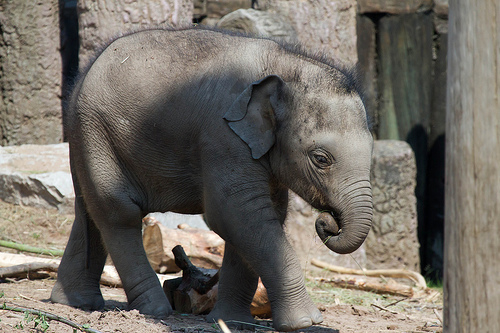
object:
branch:
[0, 239, 65, 256]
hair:
[75, 23, 371, 111]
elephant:
[47, 25, 375, 332]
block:
[278, 140, 418, 287]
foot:
[127, 291, 171, 318]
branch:
[0, 301, 89, 331]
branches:
[161, 245, 222, 315]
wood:
[157, 246, 218, 310]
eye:
[309, 150, 331, 168]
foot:
[207, 300, 258, 326]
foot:
[49, 274, 103, 309]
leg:
[72, 120, 170, 303]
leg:
[49, 140, 105, 291]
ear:
[221, 75, 295, 161]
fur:
[274, 42, 376, 116]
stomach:
[144, 176, 194, 211]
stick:
[307, 259, 429, 299]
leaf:
[3, 304, 84, 333]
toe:
[295, 307, 323, 328]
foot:
[269, 300, 325, 329]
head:
[281, 68, 377, 255]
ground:
[2, 140, 440, 332]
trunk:
[313, 175, 374, 255]